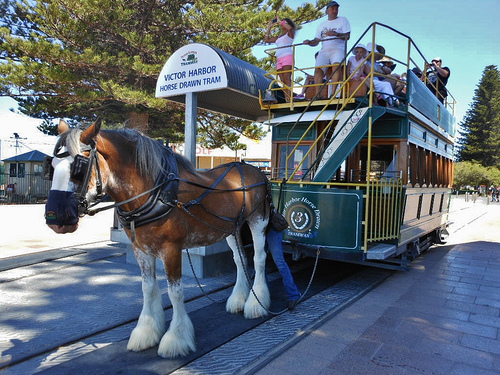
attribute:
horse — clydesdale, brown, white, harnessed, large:
[61, 125, 271, 345]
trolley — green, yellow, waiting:
[265, 38, 455, 254]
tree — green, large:
[1, 1, 283, 143]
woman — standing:
[266, 12, 298, 108]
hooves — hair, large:
[133, 287, 191, 357]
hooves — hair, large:
[232, 269, 270, 317]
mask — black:
[48, 185, 87, 224]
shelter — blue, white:
[174, 53, 271, 121]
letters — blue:
[160, 66, 220, 88]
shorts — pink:
[274, 57, 295, 66]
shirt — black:
[427, 69, 449, 97]